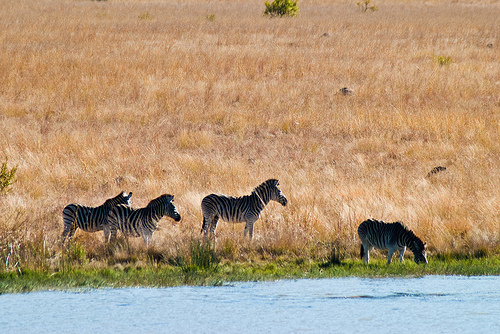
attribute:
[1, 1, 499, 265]
field — dry, brown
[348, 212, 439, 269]
zebra — eating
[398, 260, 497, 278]
grass — green, lush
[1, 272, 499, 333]
water — calm, blue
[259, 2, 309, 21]
tree — small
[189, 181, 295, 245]
zebra — walking, standing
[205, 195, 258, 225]
stripes — black, white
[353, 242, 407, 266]
legs — white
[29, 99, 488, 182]
grass — tall